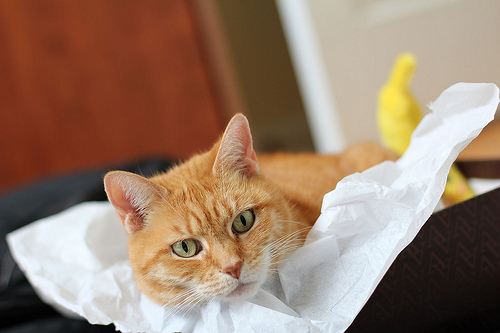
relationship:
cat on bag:
[104, 112, 403, 315] [6, 81, 499, 332]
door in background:
[0, 1, 226, 192] [0, 0, 498, 193]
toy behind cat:
[375, 53, 470, 203] [104, 112, 403, 315]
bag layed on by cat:
[6, 81, 499, 332] [104, 112, 403, 315]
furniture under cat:
[345, 160, 500, 333] [104, 112, 403, 315]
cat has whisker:
[104, 112, 403, 315] [139, 262, 217, 311]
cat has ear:
[104, 112, 403, 315] [211, 111, 255, 176]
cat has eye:
[104, 112, 403, 315] [170, 236, 203, 260]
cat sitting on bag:
[104, 112, 403, 315] [6, 81, 499, 332]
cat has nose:
[104, 112, 403, 315] [222, 258, 244, 280]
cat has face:
[104, 112, 403, 315] [129, 172, 288, 307]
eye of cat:
[229, 207, 255, 234] [104, 112, 403, 315]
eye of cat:
[170, 236, 203, 260] [104, 112, 403, 315]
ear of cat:
[211, 111, 255, 176] [104, 112, 403, 315]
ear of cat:
[102, 168, 163, 230] [104, 112, 403, 315]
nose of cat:
[222, 258, 244, 280] [104, 112, 403, 315]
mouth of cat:
[226, 278, 255, 297] [104, 112, 403, 315]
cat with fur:
[104, 112, 403, 315] [129, 142, 402, 310]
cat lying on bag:
[104, 112, 403, 315] [6, 81, 499, 332]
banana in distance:
[375, 53, 470, 203] [0, 0, 498, 224]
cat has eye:
[104, 112, 403, 315] [229, 207, 255, 234]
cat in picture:
[104, 112, 403, 315] [1, 0, 498, 333]